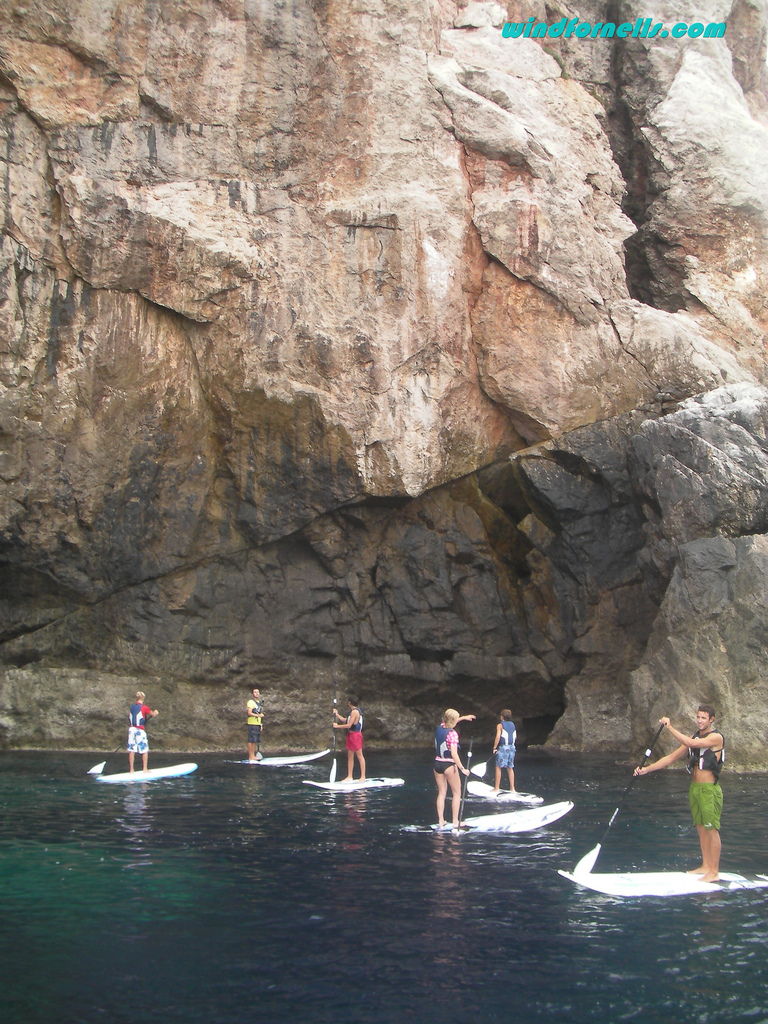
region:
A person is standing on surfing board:
[121, 689, 151, 773]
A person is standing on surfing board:
[238, 681, 264, 763]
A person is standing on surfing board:
[331, 690, 367, 774]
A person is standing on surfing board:
[422, 707, 473, 833]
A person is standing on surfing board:
[488, 705, 516, 793]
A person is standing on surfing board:
[631, 701, 724, 871]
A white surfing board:
[84, 755, 197, 780]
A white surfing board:
[229, 744, 331, 769]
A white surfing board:
[302, 771, 401, 794]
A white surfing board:
[408, 796, 576, 842]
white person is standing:
[432, 707, 475, 829]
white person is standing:
[490, 709, 521, 791]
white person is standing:
[330, 700, 368, 780]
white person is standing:
[243, 687, 264, 761]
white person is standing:
[121, 693, 155, 773]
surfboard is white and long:
[101, 758, 196, 788]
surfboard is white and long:
[240, 745, 329, 766]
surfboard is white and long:
[304, 775, 404, 789]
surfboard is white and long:
[410, 799, 574, 840]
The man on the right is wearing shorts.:
[689, 782, 723, 831]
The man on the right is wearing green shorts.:
[685, 779, 722, 827]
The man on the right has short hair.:
[691, 704, 719, 732]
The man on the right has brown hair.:
[694, 701, 712, 732]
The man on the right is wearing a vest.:
[686, 730, 725, 774]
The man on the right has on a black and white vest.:
[690, 730, 725, 776]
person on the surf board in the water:
[120, 679, 157, 771]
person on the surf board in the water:
[238, 680, 265, 754]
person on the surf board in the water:
[322, 686, 366, 783]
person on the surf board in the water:
[489, 702, 516, 794]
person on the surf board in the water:
[624, 697, 730, 889]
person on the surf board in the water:
[100, 758, 197, 788]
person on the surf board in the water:
[245, 744, 332, 774]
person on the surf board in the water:
[296, 773, 405, 791]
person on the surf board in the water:
[409, 791, 583, 849]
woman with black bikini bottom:
[409, 691, 483, 848]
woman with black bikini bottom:
[400, 687, 488, 850]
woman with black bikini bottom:
[412, 705, 487, 849]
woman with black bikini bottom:
[402, 703, 493, 842]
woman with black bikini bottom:
[413, 701, 493, 843]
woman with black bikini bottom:
[408, 699, 501, 848]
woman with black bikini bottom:
[399, 696, 487, 848]